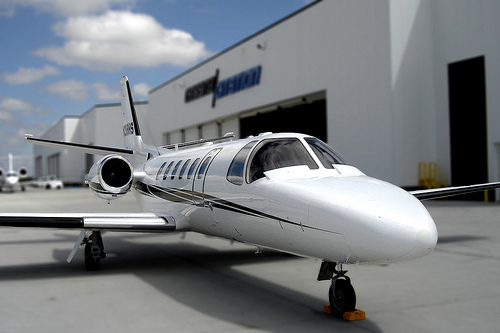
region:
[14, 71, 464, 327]
A small plane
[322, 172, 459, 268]
The nose of a plane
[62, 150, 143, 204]
The engine of a plane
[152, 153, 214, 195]
Side windows on a fuselage of a plane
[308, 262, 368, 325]
Front wheel of a plane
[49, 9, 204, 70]
A cloud in the sky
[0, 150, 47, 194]
A plane in the distance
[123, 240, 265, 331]
A shadow on the ground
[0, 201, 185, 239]
The wing of a plane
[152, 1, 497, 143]
A hangar for planes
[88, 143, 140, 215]
Silver engine of an air plane.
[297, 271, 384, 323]
Black tire of a air plane.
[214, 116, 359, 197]
Front window of a plane.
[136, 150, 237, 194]
Six side windows on a plane.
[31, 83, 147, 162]
The tail of an air plane.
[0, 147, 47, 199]
Silver air plane in back ground.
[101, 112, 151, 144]
Black letters and numbers on tail of plane.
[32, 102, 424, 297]
White and silver air plane.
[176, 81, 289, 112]
Blue and black letters on building.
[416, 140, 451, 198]
Yellow loading ramps beside building.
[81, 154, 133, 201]
Engine on the left side of the jet.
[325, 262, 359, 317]
Landing gear on the front of the small jet.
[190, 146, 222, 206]
Small side door on a white jet.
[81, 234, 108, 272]
Left side landing gear on a white jet.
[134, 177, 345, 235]
Black lines down the left side of a jet.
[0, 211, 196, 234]
White and black wing on a jet plane.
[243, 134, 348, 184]
Two windows on the very front of the jet.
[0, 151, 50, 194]
White jet in the distance.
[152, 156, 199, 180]
Five small left side windows on a jet.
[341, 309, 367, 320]
Small orange block in front of a black front wheel of a jet.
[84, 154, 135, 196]
Right side jet engine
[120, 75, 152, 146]
Airplane tail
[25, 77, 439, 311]
White and black business jet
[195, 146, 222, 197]
Airplane door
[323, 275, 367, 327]
Front wheel with blocks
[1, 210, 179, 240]
Left wing of airplane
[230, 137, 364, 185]
Cockpit front and side windows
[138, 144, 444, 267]
Fuselage of small jet airplane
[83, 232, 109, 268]
Ring wheel under right wing.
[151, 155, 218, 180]
6 right side windows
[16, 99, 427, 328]
The plane is parked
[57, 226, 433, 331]
The wheels are down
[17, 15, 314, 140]
There are clouds in the sky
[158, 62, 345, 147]
The building has writing on it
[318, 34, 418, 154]
The building is white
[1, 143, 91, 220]
There is a plane in the back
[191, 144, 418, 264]
The plane is white and black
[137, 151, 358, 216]
The plane has windows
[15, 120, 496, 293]
The plane is outside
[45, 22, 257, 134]
The sky is blue and bright